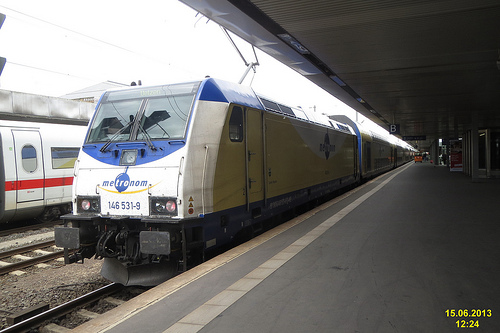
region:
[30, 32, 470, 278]
The train is coming into a station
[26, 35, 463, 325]
A train is bringing passengers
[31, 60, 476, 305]
A train is right on schedule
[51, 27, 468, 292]
A train is a little bit late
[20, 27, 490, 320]
A train is transporting commuters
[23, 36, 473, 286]
The train is on railroad tracks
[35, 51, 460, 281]
The train is stopped for passengers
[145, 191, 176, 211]
The headlights of the train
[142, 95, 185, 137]
The windshield of the train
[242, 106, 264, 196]
The door of a train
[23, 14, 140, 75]
this is the sky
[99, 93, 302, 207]
this is a train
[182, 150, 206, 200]
the train is white in color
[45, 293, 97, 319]
this is a railway line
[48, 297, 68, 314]
this is a metal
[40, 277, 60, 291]
this is a small rock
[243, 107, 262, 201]
this is a door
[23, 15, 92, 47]
this is a wire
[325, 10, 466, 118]
this is the roof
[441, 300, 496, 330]
this is a writing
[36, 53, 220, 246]
the front of a blue and white train.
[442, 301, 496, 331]
a time stamp on a picture.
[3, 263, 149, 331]
tracks near a train station.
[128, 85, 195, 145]
a window on a train.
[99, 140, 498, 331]
a loading platform at a station station.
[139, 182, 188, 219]
headlight on a train.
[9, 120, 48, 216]
door on a train.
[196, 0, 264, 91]
power line above a train.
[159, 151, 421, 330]
A line near a train.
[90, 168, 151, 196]
a company name.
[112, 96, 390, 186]
white yellow and blue train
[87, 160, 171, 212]
blue and white company name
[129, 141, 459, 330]
yellow lines on platform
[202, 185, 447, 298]
concrete on platform is grey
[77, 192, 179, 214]
white headlights on train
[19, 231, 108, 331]
dark grey train tracks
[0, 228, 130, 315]
grey gravel in tracks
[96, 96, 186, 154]
black windshield wipers on train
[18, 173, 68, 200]
red stripe on train in rear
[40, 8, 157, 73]
bright grey and cloudy sky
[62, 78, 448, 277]
train on the tracks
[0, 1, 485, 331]
two trains at the station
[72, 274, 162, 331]
thick yellow line on the ground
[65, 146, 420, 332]
two parallel lines on the ground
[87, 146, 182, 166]
blue paint on the front of the train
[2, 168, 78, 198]
thick red stripe on the train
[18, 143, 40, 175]
window on the door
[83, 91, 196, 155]
large windows on the front of the train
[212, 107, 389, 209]
side of the train is yellow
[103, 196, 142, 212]
blue numbers on the front of the train